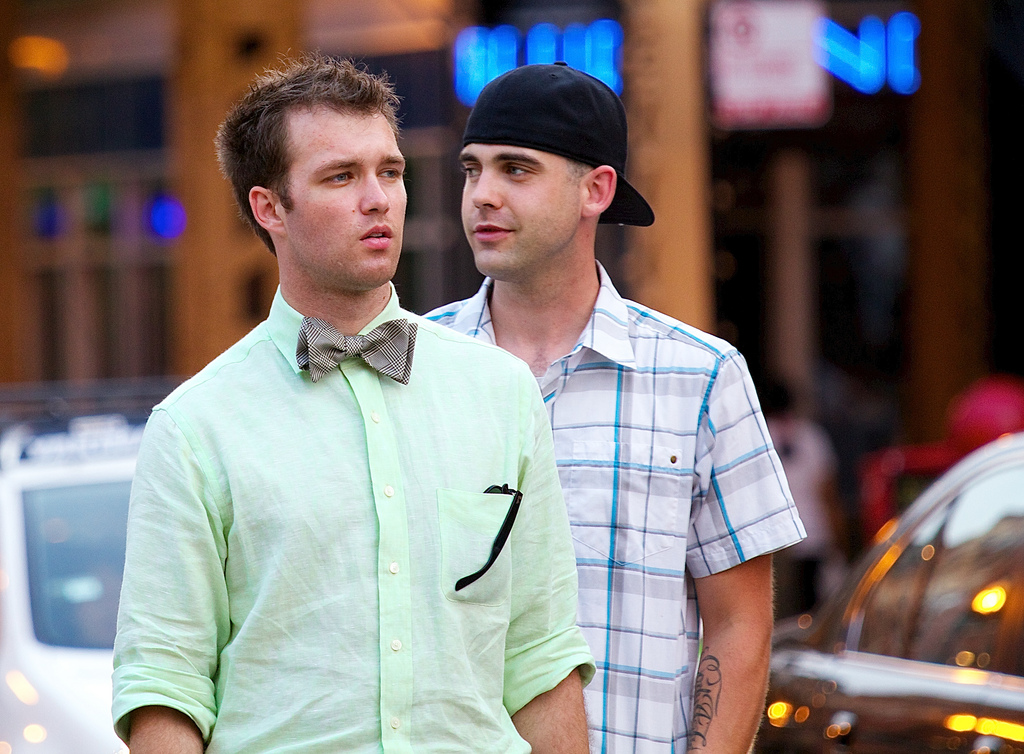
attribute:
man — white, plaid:
[442, 53, 821, 747]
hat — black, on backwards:
[455, 55, 656, 230]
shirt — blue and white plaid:
[559, 262, 819, 744]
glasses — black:
[453, 478, 529, 593]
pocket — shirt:
[436, 485, 517, 602]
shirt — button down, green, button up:
[116, 282, 603, 743]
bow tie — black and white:
[291, 310, 423, 384]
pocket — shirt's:
[427, 478, 518, 608]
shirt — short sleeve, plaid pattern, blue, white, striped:
[418, 260, 816, 744]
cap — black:
[451, 57, 659, 230]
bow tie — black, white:
[293, 312, 419, 379]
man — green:
[111, 44, 591, 749]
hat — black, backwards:
[465, 67, 656, 234]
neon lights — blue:
[455, 9, 918, 111]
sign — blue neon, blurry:
[450, 13, 921, 122]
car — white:
[3, 411, 148, 749]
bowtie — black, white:
[293, 305, 419, 386]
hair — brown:
[219, 53, 405, 261]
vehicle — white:
[0, 391, 396, 727]